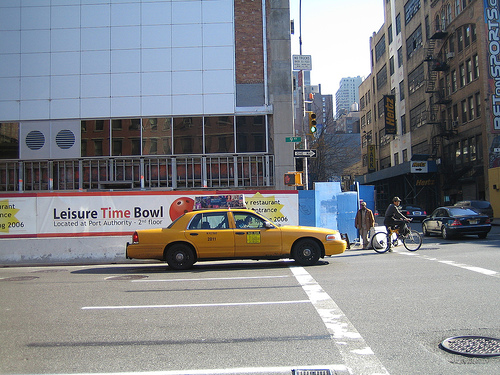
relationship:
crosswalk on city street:
[288, 232, 495, 374] [1, 217, 500, 374]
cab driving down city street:
[125, 207, 347, 269] [1, 215, 498, 374]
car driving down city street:
[419, 204, 490, 241] [1, 215, 498, 374]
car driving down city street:
[399, 203, 429, 220] [1, 215, 498, 374]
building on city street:
[358, 0, 500, 224] [392, 247, 487, 314]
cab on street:
[125, 207, 347, 269] [0, 257, 497, 372]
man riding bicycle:
[380, 194, 410, 251] [365, 215, 427, 256]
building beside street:
[357, 0, 498, 224] [0, 257, 497, 372]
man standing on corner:
[354, 202, 374, 249] [328, 243, 393, 255]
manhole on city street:
[427, 328, 497, 358] [1, 217, 500, 374]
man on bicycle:
[384, 196, 410, 252] [369, 217, 422, 252]